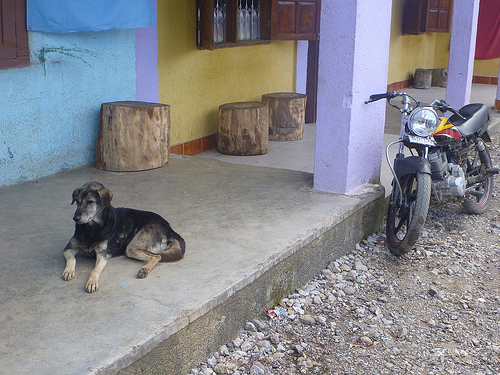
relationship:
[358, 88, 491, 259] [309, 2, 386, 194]
motorcycle propped against post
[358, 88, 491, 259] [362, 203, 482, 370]
motorcycle on gravel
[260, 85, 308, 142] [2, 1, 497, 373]
stump on porch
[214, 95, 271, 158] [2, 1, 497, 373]
stump on porch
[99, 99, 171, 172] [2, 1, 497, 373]
stump on porch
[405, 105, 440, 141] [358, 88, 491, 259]
headlight on motorcycle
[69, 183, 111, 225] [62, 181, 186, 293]
head on dog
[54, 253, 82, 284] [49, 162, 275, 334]
leg on dog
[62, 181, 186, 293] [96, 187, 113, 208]
dog has ear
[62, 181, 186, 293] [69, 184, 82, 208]
dog has ear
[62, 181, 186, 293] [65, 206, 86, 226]
dog has nose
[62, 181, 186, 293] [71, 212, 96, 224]
dog has mouth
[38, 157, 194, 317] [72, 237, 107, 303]
dog has leg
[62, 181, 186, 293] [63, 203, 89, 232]
dog has nose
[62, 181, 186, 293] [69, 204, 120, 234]
dog has neck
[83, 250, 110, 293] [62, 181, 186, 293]
leg of dog